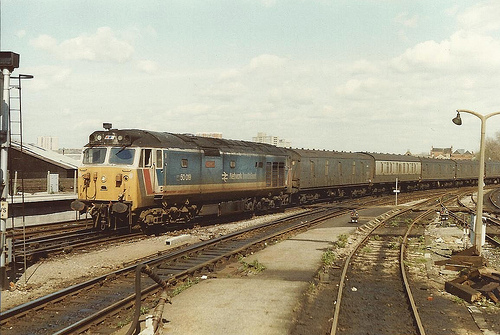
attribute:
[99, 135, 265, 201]
train — large, yellow, passing, blue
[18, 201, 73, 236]
track — rusty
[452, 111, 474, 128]
light — here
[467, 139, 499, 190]
pole — metal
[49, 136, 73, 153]
building — brown, background, distant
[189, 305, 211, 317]
ground — paved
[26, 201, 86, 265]
platform — constructed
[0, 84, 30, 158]
ladder — tall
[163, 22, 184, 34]
sky — hazy, blue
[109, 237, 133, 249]
scraps — wood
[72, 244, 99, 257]
mud — dark